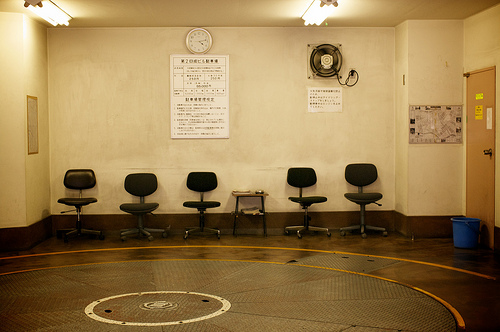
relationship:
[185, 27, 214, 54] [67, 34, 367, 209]
clock on wall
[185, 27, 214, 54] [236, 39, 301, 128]
clock hanging on wall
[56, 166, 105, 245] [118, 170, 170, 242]
chair near chair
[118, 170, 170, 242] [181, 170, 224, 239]
chair near chair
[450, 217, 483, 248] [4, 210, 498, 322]
basket on floor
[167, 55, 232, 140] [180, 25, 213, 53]
sign below clock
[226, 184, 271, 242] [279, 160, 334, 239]
table between chair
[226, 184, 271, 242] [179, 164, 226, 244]
table between chair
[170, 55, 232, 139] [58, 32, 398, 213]
directory on wall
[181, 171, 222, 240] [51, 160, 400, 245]
chair on office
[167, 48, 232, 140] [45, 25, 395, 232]
sign on wall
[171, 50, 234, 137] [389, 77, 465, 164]
directory on wall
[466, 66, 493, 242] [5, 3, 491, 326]
door to warehouse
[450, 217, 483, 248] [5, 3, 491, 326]
basket in warehouse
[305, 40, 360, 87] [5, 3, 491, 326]
fan in warehouse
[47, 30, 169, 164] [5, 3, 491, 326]
wall in warehouse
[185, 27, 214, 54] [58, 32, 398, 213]
clock on wall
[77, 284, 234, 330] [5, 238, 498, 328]
circle on floor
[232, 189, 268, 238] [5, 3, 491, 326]
table in warehouse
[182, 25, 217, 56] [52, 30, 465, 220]
clock on wall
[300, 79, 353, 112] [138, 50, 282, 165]
sign on wall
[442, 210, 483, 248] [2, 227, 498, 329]
basket on floor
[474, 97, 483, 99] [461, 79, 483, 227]
sign on door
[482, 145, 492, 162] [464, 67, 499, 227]
door handle on door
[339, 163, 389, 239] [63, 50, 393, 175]
chair against wall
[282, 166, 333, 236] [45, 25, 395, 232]
chair against wall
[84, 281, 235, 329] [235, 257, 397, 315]
circle painted floor